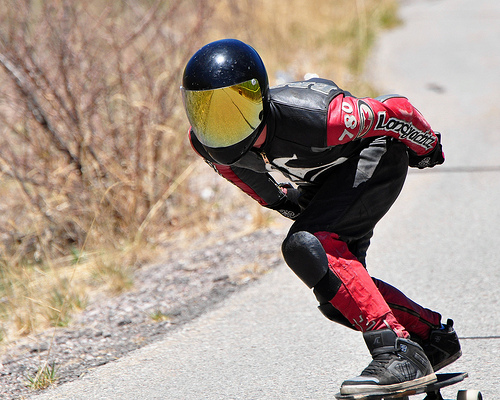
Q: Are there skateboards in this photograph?
A: Yes, there is a skateboard.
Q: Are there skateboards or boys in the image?
A: Yes, there is a skateboard.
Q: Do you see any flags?
A: No, there are no flags.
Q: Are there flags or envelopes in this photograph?
A: No, there are no flags or envelopes.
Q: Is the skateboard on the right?
A: Yes, the skateboard is on the right of the image.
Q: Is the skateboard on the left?
A: No, the skateboard is on the right of the image.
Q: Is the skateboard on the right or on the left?
A: The skateboard is on the right of the image.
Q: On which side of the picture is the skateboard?
A: The skateboard is on the right of the image.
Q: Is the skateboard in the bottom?
A: Yes, the skateboard is in the bottom of the image.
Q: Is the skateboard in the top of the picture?
A: No, the skateboard is in the bottom of the image.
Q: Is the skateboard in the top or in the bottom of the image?
A: The skateboard is in the bottom of the image.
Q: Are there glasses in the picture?
A: No, there are no glasses.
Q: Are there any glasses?
A: No, there are no glasses.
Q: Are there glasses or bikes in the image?
A: No, there are no glasses or bikes.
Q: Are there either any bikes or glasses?
A: No, there are no glasses or bikes.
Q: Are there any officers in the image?
A: No, there are no officers.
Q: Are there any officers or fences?
A: No, there are no officers or fences.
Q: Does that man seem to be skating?
A: Yes, the man is skating.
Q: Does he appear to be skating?
A: Yes, the man is skating.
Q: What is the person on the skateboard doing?
A: The man is skating.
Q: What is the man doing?
A: The man is skating.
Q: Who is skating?
A: The man is skating.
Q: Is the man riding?
A: No, the man is skating.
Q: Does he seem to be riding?
A: No, the man is skating.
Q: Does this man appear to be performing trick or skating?
A: The man is skating.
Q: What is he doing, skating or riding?
A: The man is skating.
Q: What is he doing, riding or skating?
A: The man is skating.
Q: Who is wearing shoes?
A: The man is wearing shoes.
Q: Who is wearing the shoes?
A: The man is wearing shoes.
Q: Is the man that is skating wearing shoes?
A: Yes, the man is wearing shoes.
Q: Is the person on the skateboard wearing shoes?
A: Yes, the man is wearing shoes.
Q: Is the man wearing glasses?
A: No, the man is wearing shoes.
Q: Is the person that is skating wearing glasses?
A: No, the man is wearing shoes.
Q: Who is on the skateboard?
A: The man is on the skateboard.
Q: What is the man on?
A: The man is on the skateboard.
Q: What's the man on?
A: The man is on the skateboard.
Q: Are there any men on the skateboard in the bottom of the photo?
A: Yes, there is a man on the skateboard.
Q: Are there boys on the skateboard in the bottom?
A: No, there is a man on the skateboard.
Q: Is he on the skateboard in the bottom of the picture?
A: Yes, the man is on the skateboard.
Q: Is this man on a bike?
A: No, the man is on the skateboard.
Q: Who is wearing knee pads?
A: The man is wearing knee pads.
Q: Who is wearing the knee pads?
A: The man is wearing knee pads.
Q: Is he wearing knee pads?
A: Yes, the man is wearing knee pads.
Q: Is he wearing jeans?
A: No, the man is wearing knee pads.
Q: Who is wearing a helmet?
A: The man is wearing a helmet.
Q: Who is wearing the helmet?
A: The man is wearing a helmet.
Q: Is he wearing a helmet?
A: Yes, the man is wearing a helmet.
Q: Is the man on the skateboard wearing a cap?
A: No, the man is wearing a helmet.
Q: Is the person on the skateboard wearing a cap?
A: No, the man is wearing a helmet.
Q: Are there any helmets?
A: Yes, there is a helmet.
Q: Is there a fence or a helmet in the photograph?
A: Yes, there is a helmet.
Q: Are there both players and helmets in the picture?
A: No, there is a helmet but no players.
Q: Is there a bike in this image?
A: No, there are no bikes.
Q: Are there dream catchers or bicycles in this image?
A: No, there are no bicycles or dream catchers.